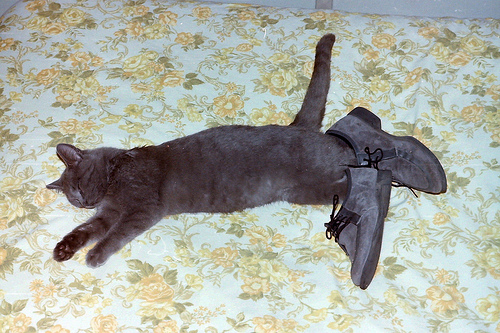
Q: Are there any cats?
A: Yes, there is a cat.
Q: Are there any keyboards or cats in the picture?
A: Yes, there is a cat.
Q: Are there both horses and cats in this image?
A: No, there is a cat but no horses.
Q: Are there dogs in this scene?
A: No, there are no dogs.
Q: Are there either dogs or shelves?
A: No, there are no dogs or shelves.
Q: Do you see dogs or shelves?
A: No, there are no dogs or shelves.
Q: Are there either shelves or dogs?
A: No, there are no dogs or shelves.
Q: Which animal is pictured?
A: The animal is a cat.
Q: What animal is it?
A: The animal is a cat.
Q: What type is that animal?
A: This is a cat.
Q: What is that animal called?
A: This is a cat.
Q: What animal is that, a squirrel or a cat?
A: This is a cat.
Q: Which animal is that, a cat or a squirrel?
A: This is a cat.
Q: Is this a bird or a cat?
A: This is a cat.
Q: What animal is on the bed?
A: The animal is a cat.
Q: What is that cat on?
A: The cat is on the bed.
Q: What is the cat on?
A: The cat is on the bed.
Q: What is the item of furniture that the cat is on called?
A: The piece of furniture is a bed.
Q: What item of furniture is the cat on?
A: The cat is on the bed.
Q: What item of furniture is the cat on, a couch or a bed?
A: The cat is on a bed.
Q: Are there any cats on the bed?
A: Yes, there is a cat on the bed.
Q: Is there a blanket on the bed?
A: No, there is a cat on the bed.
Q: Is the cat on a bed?
A: Yes, the cat is on a bed.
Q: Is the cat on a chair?
A: No, the cat is on a bed.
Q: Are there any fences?
A: No, there are no fences.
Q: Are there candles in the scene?
A: No, there are no candles.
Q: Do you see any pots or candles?
A: No, there are no candles or pots.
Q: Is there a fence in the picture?
A: No, there are no fences.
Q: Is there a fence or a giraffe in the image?
A: No, there are no fences or giraffes.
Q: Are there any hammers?
A: No, there are no hammers.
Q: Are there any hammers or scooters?
A: No, there are no hammers or scooters.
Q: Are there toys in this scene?
A: No, there are no toys.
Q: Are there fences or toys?
A: No, there are no toys or fences.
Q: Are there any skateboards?
A: No, there are no skateboards.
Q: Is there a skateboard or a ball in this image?
A: No, there are no skateboards or balls.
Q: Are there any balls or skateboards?
A: No, there are no skateboards or balls.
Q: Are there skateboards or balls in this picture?
A: No, there are no skateboards or balls.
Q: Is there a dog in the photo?
A: No, there are no dogs.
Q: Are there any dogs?
A: No, there are no dogs.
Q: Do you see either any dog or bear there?
A: No, there are no dogs or bears.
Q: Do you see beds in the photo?
A: Yes, there is a bed.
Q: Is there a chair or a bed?
A: Yes, there is a bed.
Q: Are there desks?
A: No, there are no desks.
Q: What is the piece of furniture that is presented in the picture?
A: The piece of furniture is a bed.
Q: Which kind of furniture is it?
A: The piece of furniture is a bed.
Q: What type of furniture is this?
A: This is a bed.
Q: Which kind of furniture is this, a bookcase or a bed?
A: This is a bed.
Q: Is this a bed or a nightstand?
A: This is a bed.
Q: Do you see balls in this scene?
A: No, there are no balls.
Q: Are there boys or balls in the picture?
A: No, there are no balls or boys.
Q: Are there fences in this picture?
A: No, there are no fences.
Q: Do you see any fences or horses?
A: No, there are no fences or horses.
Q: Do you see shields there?
A: No, there are no shields.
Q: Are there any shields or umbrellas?
A: No, there are no shields or umbrellas.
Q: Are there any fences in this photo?
A: No, there are no fences.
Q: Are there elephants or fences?
A: No, there are no fences or elephants.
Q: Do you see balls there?
A: No, there are no balls.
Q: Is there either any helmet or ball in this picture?
A: No, there are no balls or helmets.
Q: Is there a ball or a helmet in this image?
A: No, there are no balls or helmets.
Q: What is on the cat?
A: The shoe is on the cat.